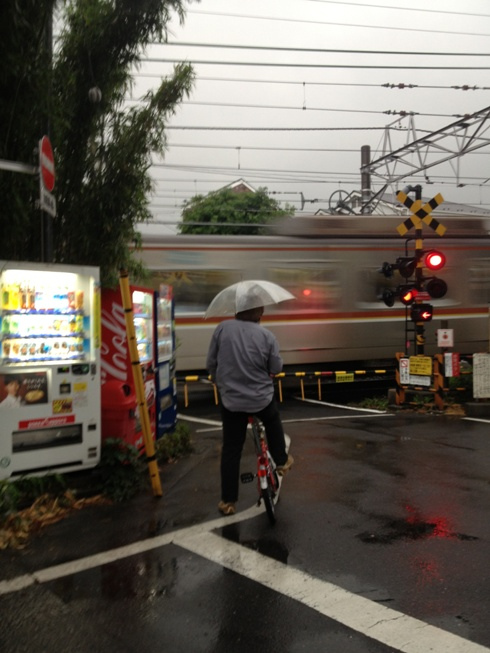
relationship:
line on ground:
[172, 529, 488, 646] [260, 552, 323, 602]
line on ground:
[0, 412, 293, 593] [260, 552, 323, 602]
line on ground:
[294, 389, 390, 413] [260, 552, 323, 602]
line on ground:
[197, 410, 488, 433] [260, 552, 323, 602]